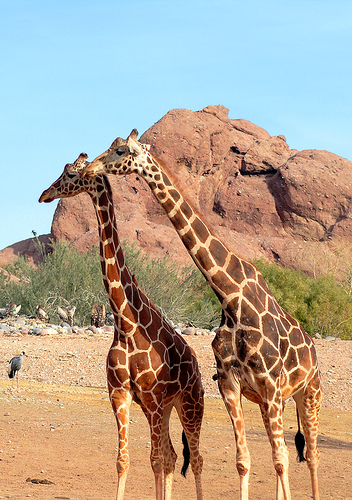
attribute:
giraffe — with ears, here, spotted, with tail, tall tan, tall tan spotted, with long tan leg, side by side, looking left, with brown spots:
[36, 149, 158, 497]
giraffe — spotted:
[88, 123, 324, 500]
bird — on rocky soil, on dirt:
[10, 349, 31, 381]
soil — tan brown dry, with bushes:
[6, 391, 108, 499]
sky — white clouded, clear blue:
[6, 6, 346, 110]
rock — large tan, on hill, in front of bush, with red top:
[184, 116, 351, 208]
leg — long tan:
[219, 379, 260, 500]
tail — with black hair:
[292, 404, 311, 465]